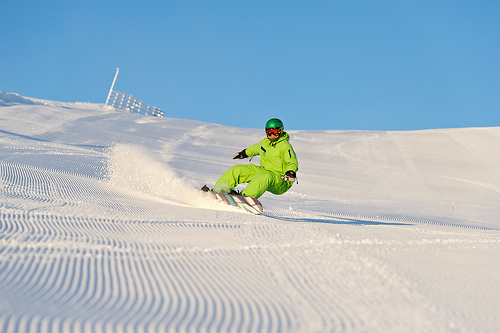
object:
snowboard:
[197, 184, 264, 217]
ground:
[0, 91, 499, 332]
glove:
[229, 147, 251, 159]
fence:
[106, 89, 166, 120]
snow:
[0, 93, 499, 333]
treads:
[0, 253, 20, 282]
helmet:
[264, 117, 284, 133]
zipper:
[286, 148, 293, 158]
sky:
[0, 0, 499, 131]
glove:
[278, 170, 300, 186]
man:
[209, 118, 298, 202]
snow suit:
[210, 132, 299, 199]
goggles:
[263, 126, 285, 136]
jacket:
[241, 132, 298, 178]